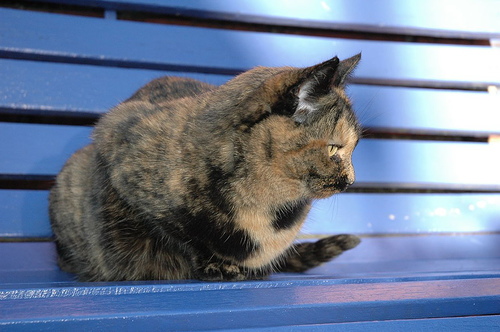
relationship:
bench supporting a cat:
[4, 2, 496, 326] [40, 42, 410, 297]